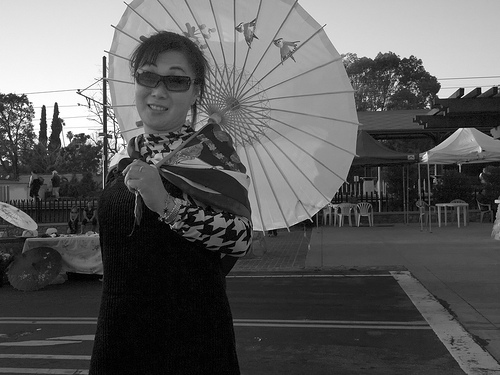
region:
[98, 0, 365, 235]
woman is holding umbrella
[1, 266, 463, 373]
white paint on street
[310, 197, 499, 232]
white plastic chairs under umbrella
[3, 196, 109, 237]
wooden fence behind people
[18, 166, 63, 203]
people walking behind fence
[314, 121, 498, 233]
canopies above tables and chairs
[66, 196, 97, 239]
people sitting on wall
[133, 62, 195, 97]
woman is wearing sunglasses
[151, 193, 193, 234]
woman is wearing bracelets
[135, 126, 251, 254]
woman has houndstooth pattern shirt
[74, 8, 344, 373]
person standing with a parasol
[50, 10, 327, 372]
woman holding a parasol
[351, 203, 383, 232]
lawn chair on ground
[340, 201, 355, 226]
lawn chair on ground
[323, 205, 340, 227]
lawn chair on ground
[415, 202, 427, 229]
lawn chair on ground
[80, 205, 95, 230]
person on the sidewalk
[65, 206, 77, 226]
person on the sidewalk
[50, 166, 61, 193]
person on the sidewalk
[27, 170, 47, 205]
person on the sidewalk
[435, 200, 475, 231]
table on the sidewalk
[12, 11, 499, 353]
a white and black photo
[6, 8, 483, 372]
a scene outside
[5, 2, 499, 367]
a photo during the day time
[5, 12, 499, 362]
a scene downtown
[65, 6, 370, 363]
a woman holding an umbrella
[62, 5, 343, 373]
a person posing for the camera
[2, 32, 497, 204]
trees in the back ground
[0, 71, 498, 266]
some power lines in the distance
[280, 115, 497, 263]
some overhead tents with white chairs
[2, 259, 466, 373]
street with some white lines